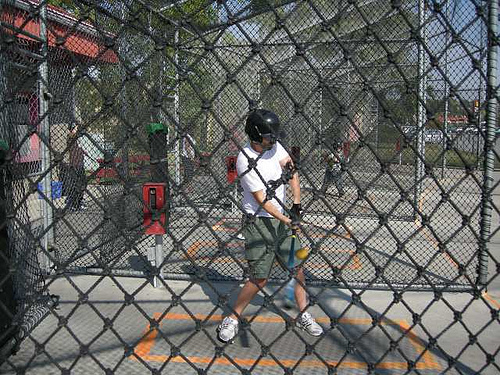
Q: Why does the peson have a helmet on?
A: To protect their head.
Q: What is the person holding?
A: A bat.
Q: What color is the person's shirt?
A: White.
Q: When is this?
A: Daytime.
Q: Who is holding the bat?
A: The batter.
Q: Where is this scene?
A: Batting cages.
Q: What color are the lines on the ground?
A: Yellow.